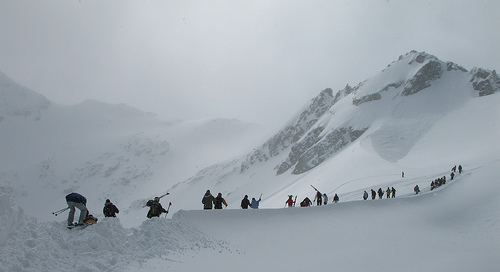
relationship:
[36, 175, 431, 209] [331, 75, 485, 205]
skiers ascending mountain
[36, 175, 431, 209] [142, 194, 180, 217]
skiers hold poles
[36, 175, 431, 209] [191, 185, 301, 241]
skiers travels by pairs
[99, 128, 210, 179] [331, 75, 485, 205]
snow covered mountain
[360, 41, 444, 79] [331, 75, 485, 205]
peak of mountain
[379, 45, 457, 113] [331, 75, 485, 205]
tip of mountain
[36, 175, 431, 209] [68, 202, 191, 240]
skiers wearing pants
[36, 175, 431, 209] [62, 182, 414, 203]
skiers wears coats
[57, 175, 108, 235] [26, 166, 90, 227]
man bending over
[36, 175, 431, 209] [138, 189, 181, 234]
skiers have backpacks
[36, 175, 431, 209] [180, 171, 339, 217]
skiers wears jackets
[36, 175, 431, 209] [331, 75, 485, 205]
skiers goes mountain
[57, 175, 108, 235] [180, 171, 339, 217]
man wears jackets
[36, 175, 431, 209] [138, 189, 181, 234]
skiers carry backpacks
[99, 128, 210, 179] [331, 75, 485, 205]
snow covers mountain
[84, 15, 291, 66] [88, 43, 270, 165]
sky covered clouds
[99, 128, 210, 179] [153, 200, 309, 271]
snow on ground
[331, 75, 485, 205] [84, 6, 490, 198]
mountain in daytime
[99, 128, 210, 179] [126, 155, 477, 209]
snow has trails